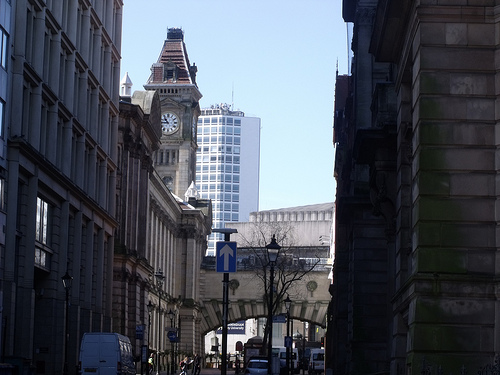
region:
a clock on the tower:
[159, 107, 180, 138]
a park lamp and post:
[263, 234, 282, 374]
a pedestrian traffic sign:
[216, 238, 238, 374]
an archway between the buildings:
[196, 299, 328, 373]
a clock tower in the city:
[142, 25, 202, 200]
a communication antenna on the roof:
[228, 72, 235, 113]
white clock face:
[160, 113, 180, 133]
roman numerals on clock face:
[158, 113, 178, 133]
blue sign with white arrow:
[216, 238, 237, 271]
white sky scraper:
[193, 84, 260, 351]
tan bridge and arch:
[202, 267, 330, 332]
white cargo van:
[78, 328, 133, 372]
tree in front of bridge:
[238, 220, 319, 369]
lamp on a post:
[258, 235, 285, 373]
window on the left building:
[33, 192, 53, 269]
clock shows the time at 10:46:
[158, 113, 178, 133]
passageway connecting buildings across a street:
[172, 241, 343, 368]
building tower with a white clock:
[146, 26, 199, 202]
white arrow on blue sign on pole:
[207, 221, 239, 373]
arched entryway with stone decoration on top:
[197, 294, 322, 371]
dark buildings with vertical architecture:
[8, 10, 203, 366]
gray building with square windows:
[195, 113, 261, 257]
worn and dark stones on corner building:
[383, 12, 497, 369]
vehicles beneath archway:
[197, 311, 321, 368]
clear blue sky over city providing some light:
[115, 4, 355, 214]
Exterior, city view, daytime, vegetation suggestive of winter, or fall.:
[4, 4, 498, 368]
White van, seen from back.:
[78, 327, 139, 374]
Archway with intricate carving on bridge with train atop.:
[205, 247, 332, 348]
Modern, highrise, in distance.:
[193, 104, 258, 235]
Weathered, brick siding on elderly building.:
[329, 40, 499, 372]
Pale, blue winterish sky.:
[220, 21, 315, 104]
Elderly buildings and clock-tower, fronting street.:
[0, 30, 200, 371]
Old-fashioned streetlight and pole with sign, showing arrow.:
[215, 222, 276, 372]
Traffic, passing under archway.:
[226, 325, 323, 370]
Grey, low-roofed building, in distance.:
[252, 204, 343, 229]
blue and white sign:
[210, 238, 237, 270]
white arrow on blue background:
[218, 246, 233, 265]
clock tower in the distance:
[153, 23, 202, 209]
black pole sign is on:
[210, 227, 243, 374]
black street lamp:
[266, 234, 279, 372]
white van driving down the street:
[83, 330, 130, 373]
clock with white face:
[158, 114, 175, 131]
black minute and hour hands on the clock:
[160, 114, 170, 124]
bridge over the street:
[202, 249, 323, 326]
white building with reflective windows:
[197, 114, 261, 249]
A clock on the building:
[163, 101, 178, 142]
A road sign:
[216, 239, 235, 279]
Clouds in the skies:
[236, 41, 295, 92]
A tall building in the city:
[391, 94, 464, 239]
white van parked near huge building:
[81, 333, 136, 370]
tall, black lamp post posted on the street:
[265, 233, 283, 373]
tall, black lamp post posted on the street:
[144, 300, 154, 372]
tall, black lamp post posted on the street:
[166, 306, 178, 371]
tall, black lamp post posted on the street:
[59, 272, 73, 372]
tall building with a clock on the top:
[149, 28, 203, 210]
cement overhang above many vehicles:
[201, 261, 331, 370]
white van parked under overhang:
[276, 348, 297, 370]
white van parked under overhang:
[309, 350, 326, 369]